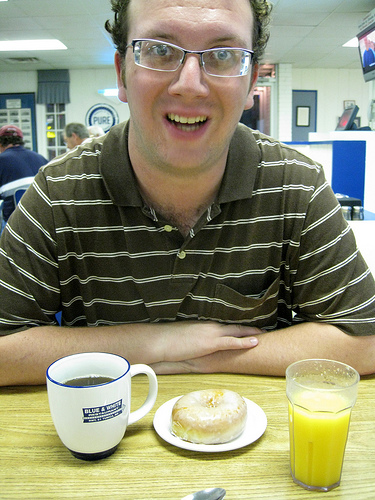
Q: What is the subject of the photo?
A: Man.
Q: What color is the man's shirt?
A: Brown.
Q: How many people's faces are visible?
A: Two.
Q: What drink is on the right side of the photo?
A: Orange juice.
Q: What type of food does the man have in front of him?
A: Donut.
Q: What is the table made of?
A: Wood.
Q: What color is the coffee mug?
A: White.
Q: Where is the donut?
A: On a plate.